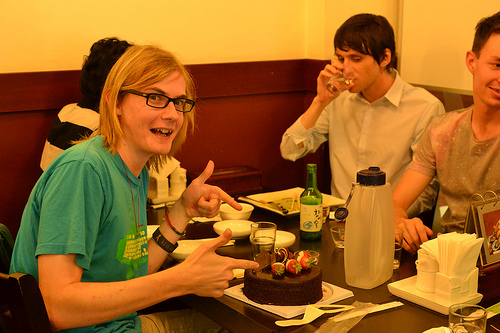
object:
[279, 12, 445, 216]
person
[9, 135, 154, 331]
shirt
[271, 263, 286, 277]
stem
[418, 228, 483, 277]
napkins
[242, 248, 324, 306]
cake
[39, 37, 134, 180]
person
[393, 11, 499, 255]
person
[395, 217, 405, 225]
wrist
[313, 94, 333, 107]
wrist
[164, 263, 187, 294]
wrist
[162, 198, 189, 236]
wrist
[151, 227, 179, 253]
bracelet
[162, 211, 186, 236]
bracelet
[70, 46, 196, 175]
hair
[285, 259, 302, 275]
strawberries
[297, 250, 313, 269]
strawberries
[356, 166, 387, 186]
top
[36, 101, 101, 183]
shirt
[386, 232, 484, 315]
holder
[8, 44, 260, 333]
man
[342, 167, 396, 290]
bottle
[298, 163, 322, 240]
bottle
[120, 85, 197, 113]
glasses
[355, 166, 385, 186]
cover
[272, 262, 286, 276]
strawberries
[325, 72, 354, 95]
water